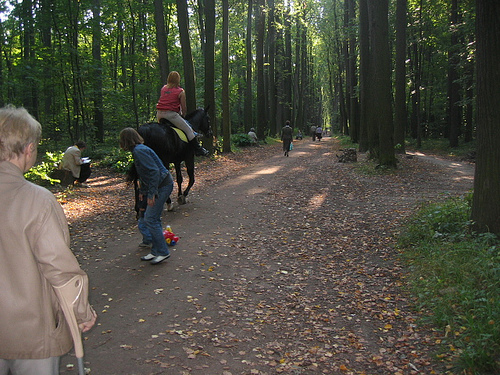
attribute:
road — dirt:
[173, 199, 344, 338]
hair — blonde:
[162, 67, 184, 88]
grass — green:
[411, 208, 487, 337]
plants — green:
[399, 216, 496, 344]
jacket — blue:
[134, 140, 169, 192]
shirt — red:
[153, 87, 174, 112]